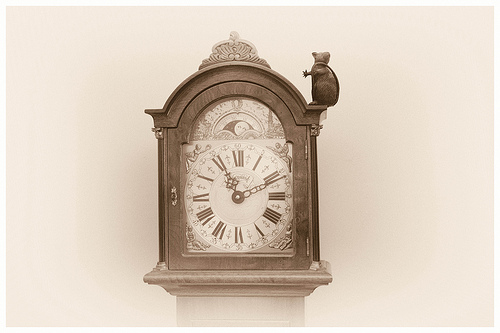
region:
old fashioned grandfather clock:
[139, 31, 340, 296]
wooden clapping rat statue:
[299, 47, 344, 110]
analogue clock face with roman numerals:
[185, 144, 294, 251]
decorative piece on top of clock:
[199, 30, 269, 73]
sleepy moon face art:
[192, 102, 282, 145]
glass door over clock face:
[159, 82, 316, 281]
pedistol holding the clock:
[141, 257, 341, 322]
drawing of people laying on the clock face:
[266, 140, 295, 171]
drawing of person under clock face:
[181, 223, 208, 251]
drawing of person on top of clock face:
[183, 143, 210, 170]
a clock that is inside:
[79, 22, 482, 330]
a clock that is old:
[53, 11, 443, 322]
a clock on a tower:
[86, 7, 405, 332]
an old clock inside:
[139, 38, 305, 239]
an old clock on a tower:
[132, 26, 447, 328]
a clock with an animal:
[119, 26, 432, 308]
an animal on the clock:
[107, 36, 304, 286]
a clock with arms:
[132, 53, 401, 317]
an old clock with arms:
[158, 56, 331, 255]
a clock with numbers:
[127, 66, 418, 326]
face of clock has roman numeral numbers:
[180, 131, 301, 248]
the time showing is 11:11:
[179, 132, 309, 258]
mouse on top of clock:
[297, 42, 347, 119]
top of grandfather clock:
[149, 53, 340, 292]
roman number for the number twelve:
[229, 141, 250, 170]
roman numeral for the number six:
[229, 222, 251, 251]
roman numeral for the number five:
[252, 221, 273, 248]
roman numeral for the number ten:
[191, 167, 221, 187]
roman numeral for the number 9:
[186, 185, 220, 207]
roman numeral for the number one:
[249, 150, 269, 179]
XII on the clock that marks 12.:
[231, 148, 246, 169]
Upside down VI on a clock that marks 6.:
[234, 224, 245, 244]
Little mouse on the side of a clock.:
[301, 49, 340, 108]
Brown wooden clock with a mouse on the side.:
[144, 32, 339, 269]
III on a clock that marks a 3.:
[266, 190, 286, 203]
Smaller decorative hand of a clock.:
[220, 160, 245, 205]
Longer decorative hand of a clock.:
[232, 174, 287, 202]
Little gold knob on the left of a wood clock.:
[167, 185, 179, 205]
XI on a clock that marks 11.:
[210, 154, 226, 172]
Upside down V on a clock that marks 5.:
[253, 221, 265, 238]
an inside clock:
[129, 28, 426, 307]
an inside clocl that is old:
[112, 18, 394, 290]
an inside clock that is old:
[134, 43, 361, 245]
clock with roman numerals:
[121, 73, 348, 298]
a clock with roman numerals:
[129, 51, 403, 308]